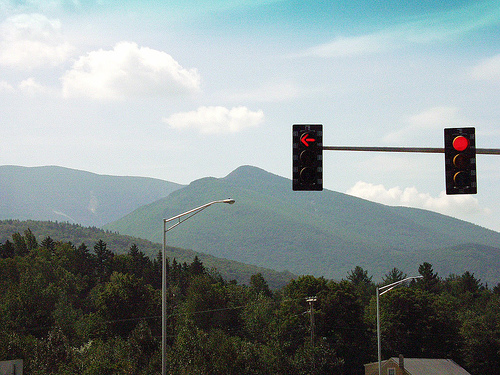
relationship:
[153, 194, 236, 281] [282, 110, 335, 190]
pole next to light